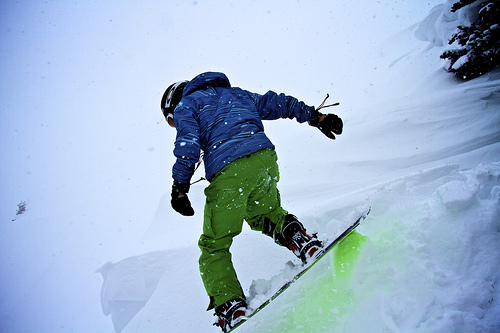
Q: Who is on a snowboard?
A: A person.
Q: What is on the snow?
A: A Snowboard.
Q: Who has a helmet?
A: A man.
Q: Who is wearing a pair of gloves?
A: A man.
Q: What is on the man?
A: Green pants.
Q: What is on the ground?
A: Snow.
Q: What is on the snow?
A: A skier.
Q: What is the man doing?
A: Snowboarding.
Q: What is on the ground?
A: Snow.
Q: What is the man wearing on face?
A: Goggles.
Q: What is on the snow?
A: Tracks.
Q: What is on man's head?
A: Helmet.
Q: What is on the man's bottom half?
A: Snow pants.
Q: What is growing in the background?
A: Tree.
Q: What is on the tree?
A: Snow.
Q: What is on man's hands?
A: Gloves.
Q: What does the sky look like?
A: Cloudy.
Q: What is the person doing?
A: Snowboarding.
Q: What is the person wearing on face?
A: Goggles.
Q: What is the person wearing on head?
A: Helmet.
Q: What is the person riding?
A: Snowboard.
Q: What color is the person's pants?
A: Green.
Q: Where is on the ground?
A: Snow.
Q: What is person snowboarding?
A: On mountain.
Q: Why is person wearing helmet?
A: Protection.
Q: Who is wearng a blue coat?
A: The snowboarder.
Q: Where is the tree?
A: Upper left corner.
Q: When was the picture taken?
A: Daytime.